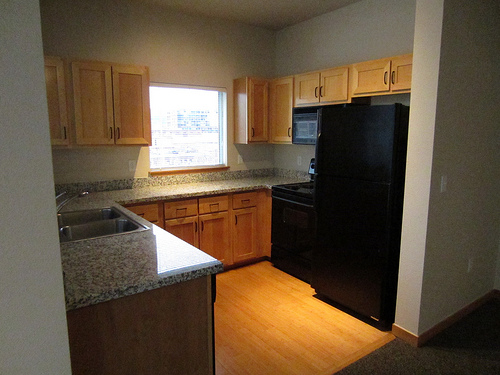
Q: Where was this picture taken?
A: A kitchen.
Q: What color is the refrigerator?
A: Black.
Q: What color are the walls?
A: Grey.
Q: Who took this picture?
A: The homeowner.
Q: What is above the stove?
A: The microwave.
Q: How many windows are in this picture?
A: One.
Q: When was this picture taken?
A: During the day.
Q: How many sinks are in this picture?
A: Two.